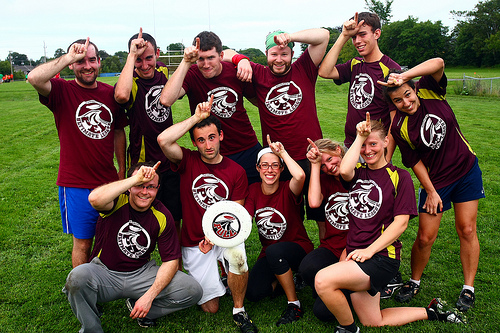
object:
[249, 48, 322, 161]
shirt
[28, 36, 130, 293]
man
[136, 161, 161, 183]
hand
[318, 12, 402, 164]
man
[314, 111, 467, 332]
girl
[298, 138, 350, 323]
girl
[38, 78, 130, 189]
shirt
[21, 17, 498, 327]
players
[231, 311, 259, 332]
shoe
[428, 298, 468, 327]
shoe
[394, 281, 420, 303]
tennis shoes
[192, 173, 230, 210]
logo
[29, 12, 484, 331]
team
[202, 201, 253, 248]
frisbee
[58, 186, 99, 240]
blue shorts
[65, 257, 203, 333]
pants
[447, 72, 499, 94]
fence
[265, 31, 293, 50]
green scarf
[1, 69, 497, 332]
grass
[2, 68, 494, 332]
ground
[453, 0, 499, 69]
tree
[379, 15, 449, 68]
tree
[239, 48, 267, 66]
tree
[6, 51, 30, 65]
tree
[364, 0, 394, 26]
tree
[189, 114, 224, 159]
head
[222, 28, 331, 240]
man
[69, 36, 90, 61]
hand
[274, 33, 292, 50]
hand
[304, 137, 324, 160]
sign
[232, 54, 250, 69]
wristband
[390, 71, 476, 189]
shirt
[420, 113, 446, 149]
logo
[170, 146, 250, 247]
shirt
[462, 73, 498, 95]
gate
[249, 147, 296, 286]
woman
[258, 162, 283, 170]
glasses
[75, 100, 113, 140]
logo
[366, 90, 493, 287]
woman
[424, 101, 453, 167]
sign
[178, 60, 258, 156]
t-shirt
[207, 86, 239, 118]
logo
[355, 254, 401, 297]
shorts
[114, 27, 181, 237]
man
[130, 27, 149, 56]
hand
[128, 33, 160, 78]
head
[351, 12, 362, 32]
sign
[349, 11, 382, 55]
head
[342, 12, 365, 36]
hand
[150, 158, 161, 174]
sign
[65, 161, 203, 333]
man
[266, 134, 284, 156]
hand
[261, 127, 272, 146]
sign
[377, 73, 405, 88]
hand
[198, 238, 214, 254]
hand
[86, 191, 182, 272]
t-shirt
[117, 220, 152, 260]
logo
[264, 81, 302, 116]
logo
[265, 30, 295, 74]
head